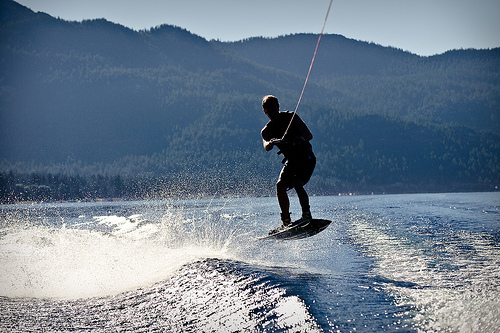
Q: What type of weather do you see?
A: It is clear.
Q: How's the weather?
A: It is clear.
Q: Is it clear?
A: Yes, it is clear.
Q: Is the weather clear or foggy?
A: It is clear.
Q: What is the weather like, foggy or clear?
A: It is clear.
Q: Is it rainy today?
A: No, it is clear.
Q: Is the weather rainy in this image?
A: No, it is clear.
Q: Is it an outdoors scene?
A: Yes, it is outdoors.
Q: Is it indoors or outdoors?
A: It is outdoors.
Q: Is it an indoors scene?
A: No, it is outdoors.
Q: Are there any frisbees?
A: No, there are no frisbees.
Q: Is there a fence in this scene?
A: No, there are no fences.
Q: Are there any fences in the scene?
A: No, there are no fences.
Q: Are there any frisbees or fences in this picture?
A: No, there are no fences or frisbees.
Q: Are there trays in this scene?
A: No, there are no trays.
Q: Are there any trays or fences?
A: No, there are no trays or fences.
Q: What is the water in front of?
A: The water is in front of the mountain.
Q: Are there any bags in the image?
A: No, there are no bags.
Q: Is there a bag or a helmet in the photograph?
A: No, there are no bags or helmets.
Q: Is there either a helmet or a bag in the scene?
A: No, there are no bags or helmets.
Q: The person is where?
A: The person is in the water.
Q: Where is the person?
A: The person is in the water.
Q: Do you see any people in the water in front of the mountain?
A: Yes, there is a person in the water.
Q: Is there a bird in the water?
A: No, there is a person in the water.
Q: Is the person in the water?
A: Yes, the person is in the water.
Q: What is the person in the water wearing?
A: The person is wearing shorts.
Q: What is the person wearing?
A: The person is wearing shorts.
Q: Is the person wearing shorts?
A: Yes, the person is wearing shorts.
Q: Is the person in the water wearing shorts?
A: Yes, the person is wearing shorts.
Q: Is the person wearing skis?
A: No, the person is wearing shorts.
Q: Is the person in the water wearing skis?
A: No, the person is wearing shorts.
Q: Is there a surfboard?
A: Yes, there is a surfboard.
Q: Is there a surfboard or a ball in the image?
A: Yes, there is a surfboard.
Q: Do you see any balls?
A: No, there are no balls.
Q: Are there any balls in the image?
A: No, there are no balls.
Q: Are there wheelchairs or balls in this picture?
A: No, there are no balls or wheelchairs.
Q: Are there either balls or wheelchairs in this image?
A: No, there are no balls or wheelchairs.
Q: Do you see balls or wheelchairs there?
A: No, there are no balls or wheelchairs.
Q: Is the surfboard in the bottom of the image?
A: Yes, the surfboard is in the bottom of the image.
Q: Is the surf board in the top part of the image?
A: No, the surf board is in the bottom of the image.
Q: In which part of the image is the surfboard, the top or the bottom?
A: The surfboard is in the bottom of the image.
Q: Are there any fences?
A: No, there are no fences.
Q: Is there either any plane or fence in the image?
A: No, there are no fences or airplanes.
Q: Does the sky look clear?
A: Yes, the sky is clear.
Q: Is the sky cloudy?
A: No, the sky is clear.